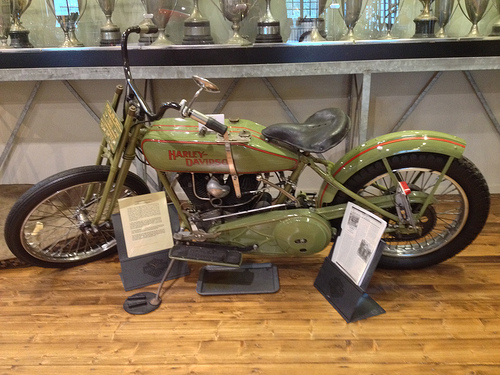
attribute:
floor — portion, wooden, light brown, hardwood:
[1, 185, 500, 375]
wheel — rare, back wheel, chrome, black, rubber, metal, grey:
[332, 152, 491, 268]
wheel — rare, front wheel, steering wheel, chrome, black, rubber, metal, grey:
[4, 165, 150, 267]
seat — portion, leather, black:
[262, 108, 351, 152]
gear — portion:
[385, 202, 436, 242]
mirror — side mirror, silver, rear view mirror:
[192, 75, 220, 93]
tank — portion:
[142, 118, 299, 173]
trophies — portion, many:
[0, 0, 499, 50]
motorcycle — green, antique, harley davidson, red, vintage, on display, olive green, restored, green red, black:
[5, 25, 490, 305]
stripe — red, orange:
[142, 125, 299, 175]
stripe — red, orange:
[319, 137, 463, 202]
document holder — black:
[112, 204, 191, 292]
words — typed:
[128, 202, 166, 242]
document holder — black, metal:
[313, 223, 386, 323]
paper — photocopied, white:
[331, 202, 387, 285]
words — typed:
[338, 218, 379, 281]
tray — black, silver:
[199, 264, 280, 296]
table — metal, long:
[1, 36, 500, 193]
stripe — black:
[0, 39, 499, 68]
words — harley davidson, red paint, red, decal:
[169, 149, 229, 166]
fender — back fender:
[318, 129, 464, 206]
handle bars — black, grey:
[122, 26, 227, 135]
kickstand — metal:
[151, 258, 176, 305]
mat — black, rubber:
[124, 292, 161, 314]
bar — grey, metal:
[0, 56, 499, 81]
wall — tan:
[1, 69, 500, 194]